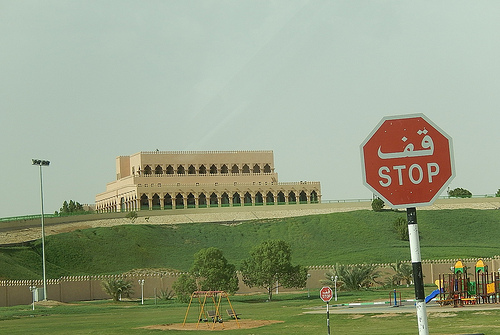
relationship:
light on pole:
[33, 158, 51, 166] [36, 165, 49, 304]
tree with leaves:
[237, 231, 302, 302] [253, 242, 282, 264]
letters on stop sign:
[381, 159, 440, 186] [365, 104, 456, 205]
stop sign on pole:
[365, 104, 456, 205] [405, 201, 433, 334]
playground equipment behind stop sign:
[426, 263, 498, 314] [365, 104, 456, 205]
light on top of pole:
[33, 158, 51, 166] [36, 165, 49, 304]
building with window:
[107, 147, 322, 205] [165, 165, 178, 171]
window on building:
[165, 165, 178, 171] [107, 147, 322, 205]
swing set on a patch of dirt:
[182, 288, 237, 333] [160, 305, 278, 334]